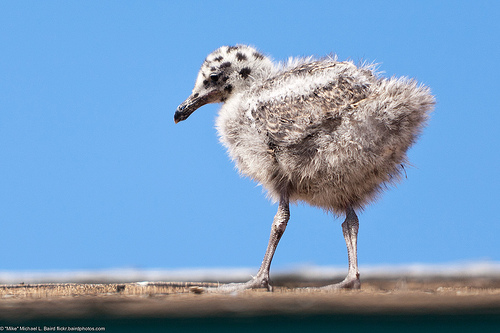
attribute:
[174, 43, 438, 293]
bird — cute, little, interesting, spotted, unique, special looking, special, out, out in daylight, young, an exotic species, exotic, standing, a baby, black, white, fluffy, not yet flying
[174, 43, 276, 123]
head — spotted, bird's, polka dotted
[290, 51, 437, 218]
tail end — slightly pointed, bushy, bird's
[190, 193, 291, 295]
leg — frail, bird's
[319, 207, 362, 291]
leg — frail, bird's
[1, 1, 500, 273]
sky — clear, blue, blue in colour, vast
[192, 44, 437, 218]
fuzz — white in color, kinky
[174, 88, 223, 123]
beak — black, bird's, small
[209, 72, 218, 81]
eye — bird's, open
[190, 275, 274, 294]
foot — apart, bird's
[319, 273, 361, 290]
foot — apart, bird's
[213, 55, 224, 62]
spot — black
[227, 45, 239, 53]
spot — black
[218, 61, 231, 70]
spot — black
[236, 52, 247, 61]
spot — black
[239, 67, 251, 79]
spot — black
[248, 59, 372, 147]
wing — bird's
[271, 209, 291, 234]
knee — bird's